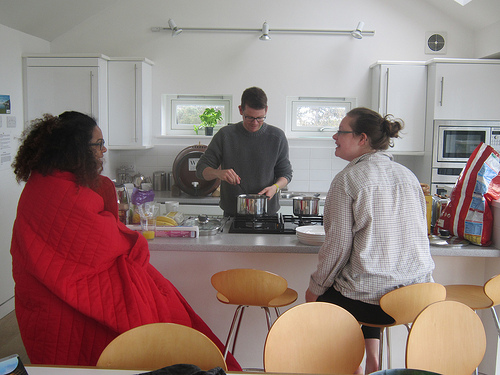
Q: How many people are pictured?
A: Three.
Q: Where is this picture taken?
A: Kitchen.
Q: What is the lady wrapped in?
A: A blanket.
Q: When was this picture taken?
A: Daytime.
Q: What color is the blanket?
A: Red.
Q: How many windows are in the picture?
A: Two.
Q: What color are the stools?
A: Light brown.